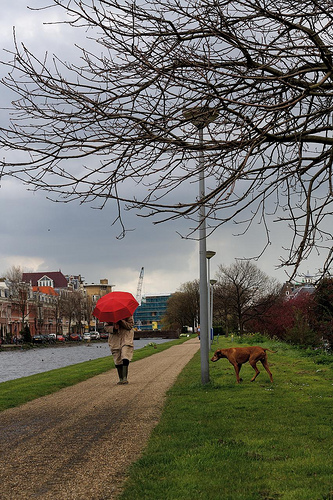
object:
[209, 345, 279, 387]
dog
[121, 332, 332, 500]
grass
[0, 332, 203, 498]
sidewalk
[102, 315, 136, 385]
man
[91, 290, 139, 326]
umbrella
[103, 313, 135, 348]
trenchcoat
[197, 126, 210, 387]
pole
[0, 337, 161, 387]
river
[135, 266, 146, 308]
crane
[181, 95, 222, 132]
light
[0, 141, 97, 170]
branches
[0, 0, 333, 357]
tree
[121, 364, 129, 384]
boots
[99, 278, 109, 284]
rooftop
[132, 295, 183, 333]
building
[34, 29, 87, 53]
air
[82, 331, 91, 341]
vehicles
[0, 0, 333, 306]
sky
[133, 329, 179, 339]
bridge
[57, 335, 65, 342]
cars